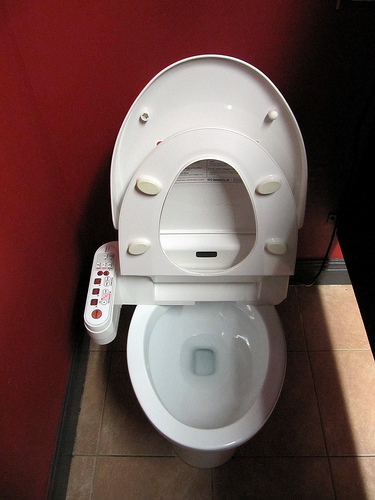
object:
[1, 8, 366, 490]
stall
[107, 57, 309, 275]
lid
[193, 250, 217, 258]
sensor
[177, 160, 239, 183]
text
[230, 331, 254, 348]
reflection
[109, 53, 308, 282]
cover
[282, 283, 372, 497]
floor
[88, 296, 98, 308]
button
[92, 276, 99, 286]
button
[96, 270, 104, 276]
button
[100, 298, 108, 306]
button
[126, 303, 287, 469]
toilet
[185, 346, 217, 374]
water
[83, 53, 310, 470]
toilet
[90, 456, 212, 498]
tile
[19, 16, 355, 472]
bathroom stall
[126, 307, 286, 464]
toilet bowl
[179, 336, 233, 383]
water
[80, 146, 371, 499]
shadow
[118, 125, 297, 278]
toilet seat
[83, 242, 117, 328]
control panel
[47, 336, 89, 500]
border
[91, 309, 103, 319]
button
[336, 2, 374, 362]
board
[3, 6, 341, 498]
wall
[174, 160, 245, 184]
sticker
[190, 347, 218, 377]
hole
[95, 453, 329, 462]
line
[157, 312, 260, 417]
bowl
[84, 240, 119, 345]
toilet arm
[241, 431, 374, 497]
tiles